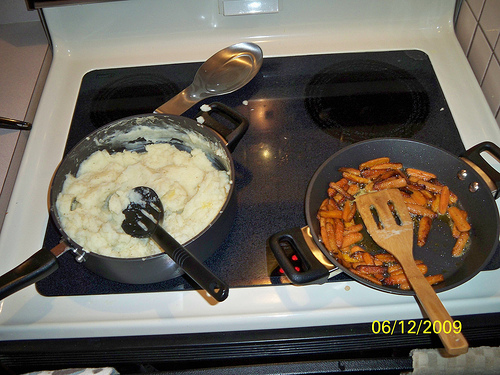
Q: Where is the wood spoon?
A: Right pan.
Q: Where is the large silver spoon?
A: On table top.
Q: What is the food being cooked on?
A: Stove.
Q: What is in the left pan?
A: Mashed potatoes.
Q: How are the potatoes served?
A: Mashed.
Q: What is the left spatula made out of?
A: Plastic.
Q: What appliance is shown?
A: Stove.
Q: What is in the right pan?
A: French fries.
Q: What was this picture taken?
A: 6/12/2009.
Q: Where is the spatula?
A: On pan.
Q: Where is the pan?
A: On stove.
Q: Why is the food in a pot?
A: Cooking.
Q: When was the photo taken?
A: During cooking.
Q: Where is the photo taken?
A: Kitchen.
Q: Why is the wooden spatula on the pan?
A: Stirring.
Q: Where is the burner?
A: On electric stove.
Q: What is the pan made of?
A: Metal.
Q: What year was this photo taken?
A: 2009.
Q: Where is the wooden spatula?
A: Right pan.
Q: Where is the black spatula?
A: Left pot.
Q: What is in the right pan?
A: Carrots.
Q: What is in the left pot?
A: Mashed potatoes.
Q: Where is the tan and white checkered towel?
A: Hanging from right side of stove.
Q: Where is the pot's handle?
A: Lower left of pot.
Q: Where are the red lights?
A: Under left pan handle.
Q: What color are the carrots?
A: Orange.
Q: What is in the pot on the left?
A: Mashed potatoes.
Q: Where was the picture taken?
A: In a kitchen.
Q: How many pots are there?
A: Two.